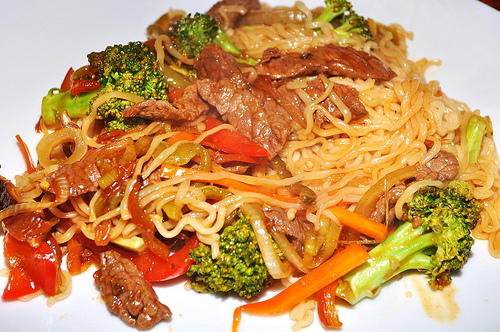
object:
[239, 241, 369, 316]
carrot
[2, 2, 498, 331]
plate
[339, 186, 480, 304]
broccoli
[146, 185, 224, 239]
noodle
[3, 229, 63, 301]
pepper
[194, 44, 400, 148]
beef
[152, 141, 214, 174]
onion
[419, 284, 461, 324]
sauce